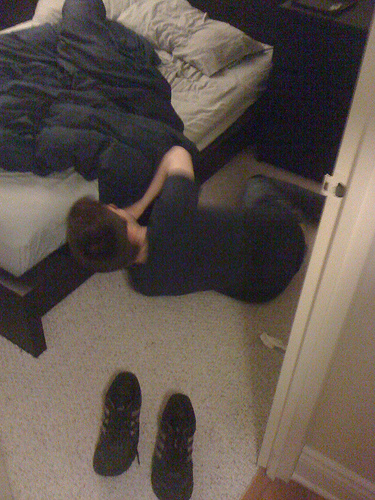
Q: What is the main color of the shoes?
A: Brown.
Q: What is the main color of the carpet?
A: White.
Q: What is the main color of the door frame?
A: White.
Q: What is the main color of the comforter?
A: Black.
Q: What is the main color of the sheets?
A: Gray.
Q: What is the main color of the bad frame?
A: Brown.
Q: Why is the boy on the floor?
A: Fell out of bed.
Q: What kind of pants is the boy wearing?
A: Jeans.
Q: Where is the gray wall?
A: Hallway.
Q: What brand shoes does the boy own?
A: Adidas.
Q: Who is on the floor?
A: The boy.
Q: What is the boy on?
A: Carpet.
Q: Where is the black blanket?
A: On the bed.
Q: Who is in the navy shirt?
A: The boy.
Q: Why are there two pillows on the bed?
A: Queen size.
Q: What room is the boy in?
A: Bedroom.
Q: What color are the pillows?
A: White.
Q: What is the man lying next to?
A: Bed.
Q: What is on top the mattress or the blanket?
A: Blanket.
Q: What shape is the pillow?
A: Rectangle.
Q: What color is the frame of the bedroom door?
A: White.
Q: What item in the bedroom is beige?
A: The carpet.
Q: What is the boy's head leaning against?
A: The bed.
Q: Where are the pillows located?
A: On the bed.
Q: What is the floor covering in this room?
A: Carpet.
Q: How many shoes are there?
A: Two.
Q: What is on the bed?
A: Blanket.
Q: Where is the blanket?
A: Bed.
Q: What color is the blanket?
A: Blue.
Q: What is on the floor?
A: Carpeting.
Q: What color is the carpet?
A: Tan.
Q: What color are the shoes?
A: Black.